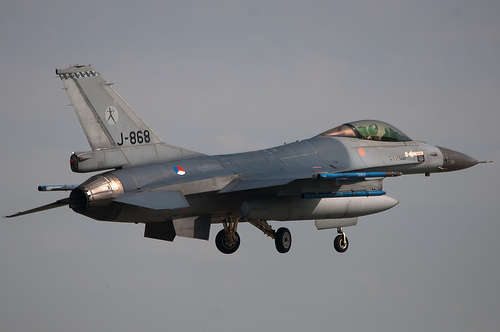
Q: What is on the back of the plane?
A: A vertical stabilizer.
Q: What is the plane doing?
A: Flying.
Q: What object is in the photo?
A: A jet.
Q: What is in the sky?
A: A jet.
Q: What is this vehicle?
A: A jet.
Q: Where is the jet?
A: In the sky.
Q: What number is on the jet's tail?
A: J-868.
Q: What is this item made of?
A: Metal.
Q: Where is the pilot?
A: Inside the jet.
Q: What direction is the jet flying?
A: To the right.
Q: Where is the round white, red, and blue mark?
A: On the side of the jet.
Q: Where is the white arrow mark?
A: Next to the cockpit.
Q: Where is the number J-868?
A: On the jet's tail.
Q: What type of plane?
A: Fighter jet.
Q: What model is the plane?
A: J-868.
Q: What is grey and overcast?
A: The sky.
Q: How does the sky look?
A: Grey and cloudy.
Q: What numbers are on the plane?
A: 868.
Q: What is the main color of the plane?
A: Grey.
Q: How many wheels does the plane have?
A: 3.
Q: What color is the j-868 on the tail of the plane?
A: Black.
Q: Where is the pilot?
A: In the cockpit.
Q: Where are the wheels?
A: Below the plane.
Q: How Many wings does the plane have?
A: 2.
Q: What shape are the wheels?
A: Circles.